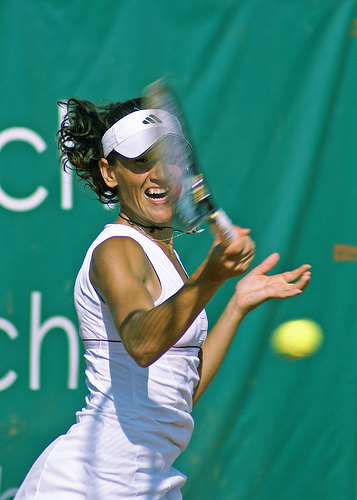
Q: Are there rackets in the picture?
A: Yes, there is a racket.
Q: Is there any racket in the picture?
A: Yes, there is a racket.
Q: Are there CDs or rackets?
A: Yes, there is a racket.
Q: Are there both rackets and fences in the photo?
A: No, there is a racket but no fences.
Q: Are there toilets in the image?
A: No, there are no toilets.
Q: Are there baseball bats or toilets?
A: No, there are no toilets or baseball bats.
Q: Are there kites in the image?
A: No, there are no kites.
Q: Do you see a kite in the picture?
A: No, there are no kites.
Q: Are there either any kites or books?
A: No, there are no kites or books.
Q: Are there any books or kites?
A: No, there are no kites or books.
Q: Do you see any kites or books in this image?
A: No, there are no kites or books.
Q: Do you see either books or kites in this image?
A: No, there are no kites or books.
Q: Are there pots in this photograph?
A: No, there are no pots.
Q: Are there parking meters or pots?
A: No, there are no pots or parking meters.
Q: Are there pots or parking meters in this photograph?
A: No, there are no pots or parking meters.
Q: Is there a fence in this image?
A: No, there are no fences.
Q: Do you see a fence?
A: No, there are no fences.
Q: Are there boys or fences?
A: No, there are no fences or boys.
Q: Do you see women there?
A: Yes, there is a woman.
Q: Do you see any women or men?
A: Yes, there is a woman.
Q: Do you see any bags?
A: No, there are no bags.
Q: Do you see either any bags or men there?
A: No, there are no bags or men.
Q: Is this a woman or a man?
A: This is a woman.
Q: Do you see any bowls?
A: No, there are no bowls.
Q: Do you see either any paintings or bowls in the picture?
A: No, there are no bowls or paintings.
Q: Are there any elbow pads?
A: No, there are no elbow pads.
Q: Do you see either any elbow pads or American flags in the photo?
A: No, there are no elbow pads or American flags.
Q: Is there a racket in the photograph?
A: Yes, there is a racket.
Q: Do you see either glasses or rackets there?
A: Yes, there is a racket.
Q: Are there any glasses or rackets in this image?
A: Yes, there is a racket.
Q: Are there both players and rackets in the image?
A: Yes, there are both a racket and a player.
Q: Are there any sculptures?
A: No, there are no sculptures.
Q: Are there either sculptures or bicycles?
A: No, there are no sculptures or bicycles.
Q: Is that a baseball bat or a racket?
A: That is a racket.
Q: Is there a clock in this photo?
A: No, there are no clocks.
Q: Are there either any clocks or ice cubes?
A: No, there are no clocks or ice cubes.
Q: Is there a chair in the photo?
A: No, there are no chairs.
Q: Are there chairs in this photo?
A: No, there are no chairs.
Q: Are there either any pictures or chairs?
A: No, there are no chairs or pictures.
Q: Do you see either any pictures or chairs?
A: No, there are no chairs or pictures.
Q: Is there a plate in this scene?
A: No, there are no plates.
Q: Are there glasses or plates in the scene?
A: No, there are no plates or glasses.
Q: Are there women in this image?
A: Yes, there is a woman.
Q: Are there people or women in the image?
A: Yes, there is a woman.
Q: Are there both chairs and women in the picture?
A: No, there is a woman but no chairs.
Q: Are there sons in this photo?
A: No, there are no sons.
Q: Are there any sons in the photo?
A: No, there are no sons.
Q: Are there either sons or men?
A: No, there are no sons or men.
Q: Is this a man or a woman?
A: This is a woman.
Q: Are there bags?
A: No, there are no bags.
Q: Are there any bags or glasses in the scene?
A: No, there are no bags or glasses.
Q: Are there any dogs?
A: No, there are no dogs.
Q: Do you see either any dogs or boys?
A: No, there are no dogs or boys.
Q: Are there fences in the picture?
A: No, there are no fences.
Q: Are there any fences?
A: No, there are no fences.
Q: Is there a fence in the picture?
A: No, there are no fences.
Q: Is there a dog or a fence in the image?
A: No, there are no fences or dogs.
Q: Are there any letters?
A: Yes, there are letters.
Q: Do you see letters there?
A: Yes, there are letters.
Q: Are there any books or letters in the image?
A: Yes, there are letters.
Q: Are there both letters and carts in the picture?
A: No, there are letters but no carts.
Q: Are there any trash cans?
A: No, there are no trash cans.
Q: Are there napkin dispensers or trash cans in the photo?
A: No, there are no trash cans or napkin dispensers.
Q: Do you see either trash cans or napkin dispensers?
A: No, there are no trash cans or napkin dispensers.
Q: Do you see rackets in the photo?
A: Yes, there is a racket.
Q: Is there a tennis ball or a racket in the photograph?
A: Yes, there is a racket.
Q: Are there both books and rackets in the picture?
A: No, there is a racket but no books.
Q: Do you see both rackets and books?
A: No, there is a racket but no books.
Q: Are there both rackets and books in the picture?
A: No, there is a racket but no books.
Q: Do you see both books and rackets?
A: No, there is a racket but no books.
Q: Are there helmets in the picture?
A: No, there are no helmets.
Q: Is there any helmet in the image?
A: No, there are no helmets.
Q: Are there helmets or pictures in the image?
A: No, there are no helmets or pictures.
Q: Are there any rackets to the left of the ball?
A: Yes, there is a racket to the left of the ball.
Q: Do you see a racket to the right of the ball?
A: No, the racket is to the left of the ball.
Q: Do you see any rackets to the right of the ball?
A: No, the racket is to the left of the ball.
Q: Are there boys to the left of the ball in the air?
A: No, there is a racket to the left of the ball.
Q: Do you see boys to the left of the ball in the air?
A: No, there is a racket to the left of the ball.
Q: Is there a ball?
A: Yes, there is a ball.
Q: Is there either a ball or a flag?
A: Yes, there is a ball.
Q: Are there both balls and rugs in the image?
A: No, there is a ball but no rugs.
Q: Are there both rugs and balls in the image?
A: No, there is a ball but no rugs.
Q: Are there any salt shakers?
A: No, there are no salt shakers.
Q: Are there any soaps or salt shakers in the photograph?
A: No, there are no salt shakers or soaps.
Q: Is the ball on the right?
A: Yes, the ball is on the right of the image.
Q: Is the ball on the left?
A: No, the ball is on the right of the image.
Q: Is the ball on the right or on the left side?
A: The ball is on the right of the image.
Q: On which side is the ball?
A: The ball is on the right of the image.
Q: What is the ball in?
A: The ball is in the air.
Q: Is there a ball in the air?
A: Yes, there is a ball in the air.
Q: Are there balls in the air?
A: Yes, there is a ball in the air.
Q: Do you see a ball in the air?
A: Yes, there is a ball in the air.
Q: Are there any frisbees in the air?
A: No, there is a ball in the air.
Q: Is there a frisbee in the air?
A: No, there is a ball in the air.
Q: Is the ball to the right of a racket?
A: Yes, the ball is to the right of a racket.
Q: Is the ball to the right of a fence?
A: No, the ball is to the right of a racket.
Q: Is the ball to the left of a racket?
A: No, the ball is to the right of a racket.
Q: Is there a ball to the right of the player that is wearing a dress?
A: Yes, there is a ball to the right of the player.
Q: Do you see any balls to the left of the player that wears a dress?
A: No, the ball is to the right of the player.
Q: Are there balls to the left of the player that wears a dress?
A: No, the ball is to the right of the player.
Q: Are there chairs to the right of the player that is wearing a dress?
A: No, there is a ball to the right of the player.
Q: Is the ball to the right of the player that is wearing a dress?
A: Yes, the ball is to the right of the player.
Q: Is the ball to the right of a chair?
A: No, the ball is to the right of the player.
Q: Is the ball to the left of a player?
A: No, the ball is to the right of a player.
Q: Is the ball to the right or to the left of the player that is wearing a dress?
A: The ball is to the right of the player.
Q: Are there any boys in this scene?
A: No, there are no boys.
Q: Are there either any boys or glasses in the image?
A: No, there are no boys or glasses.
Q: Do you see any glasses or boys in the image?
A: No, there are no boys or glasses.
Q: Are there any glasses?
A: No, there are no glasses.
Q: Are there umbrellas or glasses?
A: No, there are no glasses or umbrellas.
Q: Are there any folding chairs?
A: No, there are no folding chairs.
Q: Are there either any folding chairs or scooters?
A: No, there are no folding chairs or scooters.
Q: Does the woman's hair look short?
A: Yes, the hair is short.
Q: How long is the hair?
A: The hair is short.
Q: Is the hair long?
A: No, the hair is short.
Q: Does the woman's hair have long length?
A: No, the hair is short.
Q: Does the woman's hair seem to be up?
A: Yes, the hair is up.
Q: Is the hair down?
A: No, the hair is up.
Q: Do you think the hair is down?
A: No, the hair is up.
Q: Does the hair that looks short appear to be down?
A: No, the hair is up.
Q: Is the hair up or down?
A: The hair is up.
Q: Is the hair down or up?
A: The hair is up.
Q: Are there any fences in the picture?
A: No, there are no fences.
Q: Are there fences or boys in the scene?
A: No, there are no fences or boys.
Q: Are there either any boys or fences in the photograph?
A: No, there are no fences or boys.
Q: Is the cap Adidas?
A: Yes, the cap is adidas.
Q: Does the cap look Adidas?
A: Yes, the cap is adidas.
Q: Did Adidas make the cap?
A: Yes, the cap was made by adidas.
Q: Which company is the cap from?
A: The cap is from adidas.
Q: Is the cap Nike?
A: No, the cap is adidas.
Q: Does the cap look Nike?
A: No, the cap is adidas.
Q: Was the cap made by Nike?
A: No, the cap was made by adidas.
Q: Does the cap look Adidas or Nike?
A: The cap is adidas.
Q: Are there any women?
A: Yes, there is a woman.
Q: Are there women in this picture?
A: Yes, there is a woman.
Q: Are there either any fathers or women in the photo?
A: Yes, there is a woman.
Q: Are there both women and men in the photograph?
A: No, there is a woman but no men.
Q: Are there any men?
A: No, there are no men.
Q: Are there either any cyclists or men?
A: No, there are no men or cyclists.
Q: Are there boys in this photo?
A: No, there are no boys.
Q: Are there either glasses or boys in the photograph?
A: No, there are no boys or glasses.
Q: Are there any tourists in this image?
A: No, there are no tourists.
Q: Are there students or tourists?
A: No, there are no tourists or students.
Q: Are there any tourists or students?
A: No, there are no tourists or students.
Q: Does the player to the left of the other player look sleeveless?
A: Yes, the player is sleeveless.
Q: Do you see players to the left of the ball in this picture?
A: Yes, there is a player to the left of the ball.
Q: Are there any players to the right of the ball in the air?
A: No, the player is to the left of the ball.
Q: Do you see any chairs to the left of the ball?
A: No, there is a player to the left of the ball.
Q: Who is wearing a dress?
A: The player is wearing a dress.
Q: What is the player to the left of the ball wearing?
A: The player is wearing a dress.